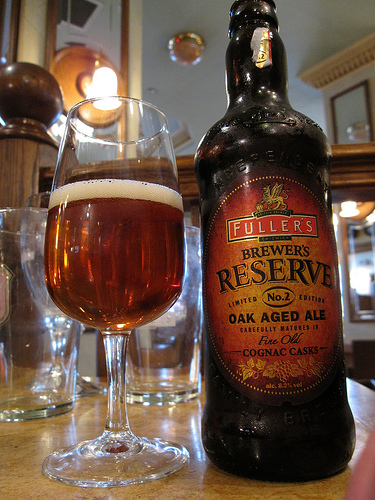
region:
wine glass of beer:
[60, 113, 162, 378]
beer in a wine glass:
[54, 172, 152, 260]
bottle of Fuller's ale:
[200, 27, 345, 449]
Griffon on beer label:
[245, 183, 295, 221]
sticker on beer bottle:
[231, 24, 300, 98]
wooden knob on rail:
[8, 66, 61, 150]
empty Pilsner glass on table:
[7, 225, 77, 410]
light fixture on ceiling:
[154, 24, 202, 80]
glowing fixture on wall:
[58, 44, 116, 108]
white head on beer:
[61, 169, 151, 234]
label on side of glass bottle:
[195, 168, 357, 409]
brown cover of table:
[178, 472, 230, 498]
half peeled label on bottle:
[243, 27, 276, 72]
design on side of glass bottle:
[249, 181, 294, 215]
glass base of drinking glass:
[37, 422, 197, 491]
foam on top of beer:
[39, 183, 182, 202]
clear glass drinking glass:
[0, 207, 87, 413]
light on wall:
[78, 61, 125, 108]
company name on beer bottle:
[228, 216, 315, 237]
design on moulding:
[298, 55, 359, 85]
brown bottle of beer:
[195, 2, 345, 479]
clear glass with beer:
[42, 99, 188, 487]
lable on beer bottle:
[210, 173, 338, 399]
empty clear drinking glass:
[3, 208, 82, 418]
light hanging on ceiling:
[339, 200, 359, 218]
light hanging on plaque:
[72, 52, 120, 113]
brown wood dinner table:
[5, 357, 374, 499]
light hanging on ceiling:
[164, 29, 208, 69]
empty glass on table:
[128, 198, 199, 406]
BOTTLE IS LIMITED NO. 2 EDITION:
[227, 283, 333, 307]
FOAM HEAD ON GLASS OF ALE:
[36, 167, 186, 216]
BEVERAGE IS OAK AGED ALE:
[230, 304, 330, 322]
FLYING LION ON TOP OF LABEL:
[247, 180, 302, 210]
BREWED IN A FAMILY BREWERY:
[200, 360, 373, 423]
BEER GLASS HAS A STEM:
[88, 318, 166, 473]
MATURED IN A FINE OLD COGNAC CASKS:
[234, 333, 340, 358]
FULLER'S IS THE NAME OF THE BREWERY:
[224, 192, 322, 237]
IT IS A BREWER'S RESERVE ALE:
[213, 241, 349, 295]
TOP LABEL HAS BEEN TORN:
[236, 23, 295, 66]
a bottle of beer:
[193, 0, 356, 481]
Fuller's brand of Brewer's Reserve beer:
[191, 0, 356, 482]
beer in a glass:
[43, 95, 186, 487]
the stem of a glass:
[102, 331, 130, 434]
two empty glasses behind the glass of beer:
[0, 205, 201, 421]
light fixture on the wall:
[54, 47, 122, 128]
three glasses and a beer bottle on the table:
[1, 1, 372, 487]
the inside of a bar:
[1, 1, 372, 498]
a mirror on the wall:
[329, 80, 371, 145]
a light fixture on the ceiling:
[168, 32, 204, 66]